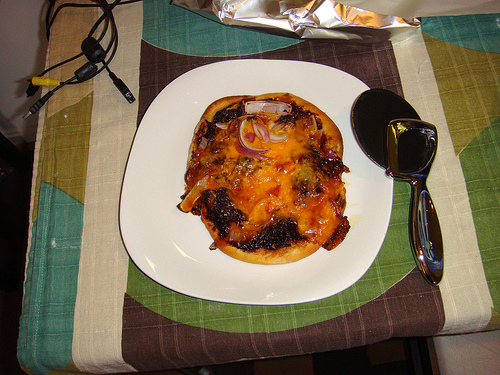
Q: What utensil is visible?
A: Pizza wheel.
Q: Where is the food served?
A: White plate.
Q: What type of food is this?
A: Pizza.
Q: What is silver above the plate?
A: Aluminum foil.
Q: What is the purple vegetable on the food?
A: Onions.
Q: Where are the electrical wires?
A: Left side of plate.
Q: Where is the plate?
A: On a table.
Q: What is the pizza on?
A: White plate.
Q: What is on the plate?
A: Pizza.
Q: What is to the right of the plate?
A: Pizza cutter.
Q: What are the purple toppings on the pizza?
A: Onions.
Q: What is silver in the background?
A: Tinfoil.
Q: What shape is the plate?
A: Square.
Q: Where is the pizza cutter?
A: On the table.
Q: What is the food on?
A: Plate.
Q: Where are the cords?
A: Table.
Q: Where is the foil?
A: Table.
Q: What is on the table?
A: Tablecloth.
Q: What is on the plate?
A: Pizza.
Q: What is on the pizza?
A: Onions.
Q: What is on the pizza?
A: Cheese.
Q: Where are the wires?
A: On the table.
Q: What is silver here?
A: Foil.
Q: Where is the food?
A: Plate.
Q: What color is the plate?
A: White.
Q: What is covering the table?
A: Tablecloth.